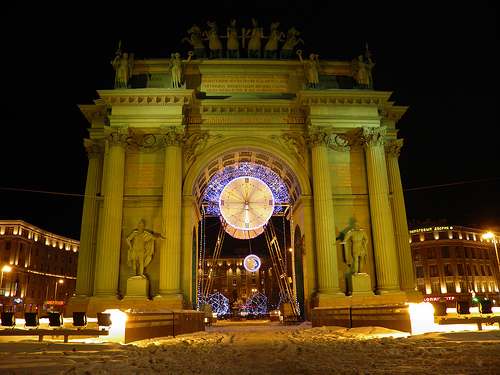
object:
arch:
[182, 134, 314, 312]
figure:
[182, 129, 210, 161]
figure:
[268, 130, 309, 165]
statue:
[124, 218, 166, 303]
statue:
[340, 220, 373, 296]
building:
[406, 219, 499, 317]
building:
[2, 219, 79, 321]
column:
[92, 135, 126, 300]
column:
[309, 138, 340, 292]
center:
[187, 167, 311, 231]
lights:
[239, 162, 255, 173]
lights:
[200, 219, 226, 320]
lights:
[265, 214, 298, 320]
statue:
[109, 39, 132, 92]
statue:
[167, 47, 194, 90]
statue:
[297, 50, 322, 91]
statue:
[350, 41, 374, 88]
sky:
[2, 1, 499, 217]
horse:
[178, 27, 205, 52]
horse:
[201, 21, 222, 53]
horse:
[222, 17, 242, 52]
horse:
[247, 16, 267, 51]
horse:
[264, 18, 283, 51]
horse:
[281, 25, 304, 50]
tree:
[202, 292, 228, 321]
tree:
[245, 292, 270, 317]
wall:
[135, 313, 184, 335]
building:
[67, 18, 436, 334]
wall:
[311, 305, 405, 324]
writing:
[201, 75, 290, 94]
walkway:
[210, 323, 280, 375]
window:
[430, 284, 441, 296]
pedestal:
[158, 125, 187, 309]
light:
[481, 229, 495, 242]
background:
[4, 213, 500, 340]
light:
[55, 277, 66, 286]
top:
[111, 29, 377, 96]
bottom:
[308, 278, 433, 337]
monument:
[66, 17, 440, 337]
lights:
[208, 291, 229, 315]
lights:
[248, 289, 270, 316]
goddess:
[109, 39, 131, 93]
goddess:
[352, 46, 378, 89]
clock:
[213, 174, 278, 239]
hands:
[243, 177, 250, 204]